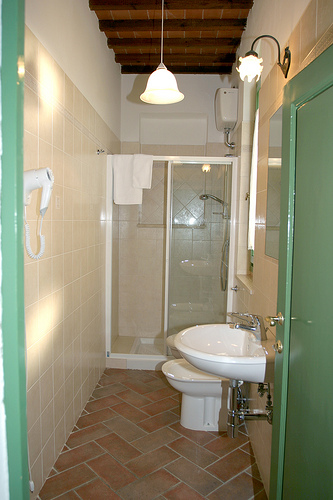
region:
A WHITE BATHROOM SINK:
[169, 306, 274, 426]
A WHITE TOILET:
[152, 357, 233, 435]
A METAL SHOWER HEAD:
[199, 191, 227, 208]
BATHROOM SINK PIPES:
[218, 383, 263, 442]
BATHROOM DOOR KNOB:
[264, 308, 287, 332]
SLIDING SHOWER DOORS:
[111, 155, 239, 367]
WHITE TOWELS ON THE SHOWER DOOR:
[96, 142, 162, 213]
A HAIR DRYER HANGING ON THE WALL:
[24, 165, 64, 264]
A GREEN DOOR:
[264, 40, 330, 497]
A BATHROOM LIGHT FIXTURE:
[231, 31, 294, 85]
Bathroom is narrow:
[17, 9, 274, 491]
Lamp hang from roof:
[132, 2, 189, 114]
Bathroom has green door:
[256, 43, 329, 498]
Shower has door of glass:
[95, 142, 238, 370]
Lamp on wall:
[233, 28, 296, 87]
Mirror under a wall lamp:
[257, 99, 285, 264]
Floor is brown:
[47, 363, 253, 497]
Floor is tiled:
[72, 362, 248, 499]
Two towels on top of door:
[105, 145, 156, 209]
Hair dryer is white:
[24, 156, 59, 265]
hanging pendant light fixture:
[137, 1, 188, 105]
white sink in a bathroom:
[176, 325, 268, 377]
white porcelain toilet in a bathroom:
[162, 358, 239, 430]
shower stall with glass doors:
[105, 153, 237, 374]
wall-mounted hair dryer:
[24, 167, 55, 260]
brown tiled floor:
[73, 438, 247, 496]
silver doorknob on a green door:
[265, 311, 284, 328]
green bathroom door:
[290, 76, 329, 496]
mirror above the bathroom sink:
[265, 101, 283, 263]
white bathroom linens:
[108, 151, 154, 206]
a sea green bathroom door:
[259, 54, 330, 492]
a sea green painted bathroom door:
[246, 59, 328, 498]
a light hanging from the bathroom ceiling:
[112, 6, 204, 126]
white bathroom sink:
[161, 299, 294, 394]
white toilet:
[146, 342, 250, 451]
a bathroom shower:
[99, 137, 248, 379]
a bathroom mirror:
[227, 96, 298, 272]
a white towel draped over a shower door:
[100, 144, 238, 378]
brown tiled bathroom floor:
[92, 366, 261, 499]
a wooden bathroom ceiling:
[114, 0, 248, 78]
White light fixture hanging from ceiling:
[134, 1, 183, 113]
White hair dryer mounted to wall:
[20, 156, 59, 261]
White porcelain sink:
[170, 315, 276, 387]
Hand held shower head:
[196, 185, 230, 292]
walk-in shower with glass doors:
[101, 152, 231, 368]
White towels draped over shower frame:
[109, 146, 166, 277]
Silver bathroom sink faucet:
[226, 303, 267, 342]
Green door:
[266, 47, 332, 498]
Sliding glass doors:
[104, 150, 228, 353]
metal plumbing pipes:
[221, 381, 276, 443]